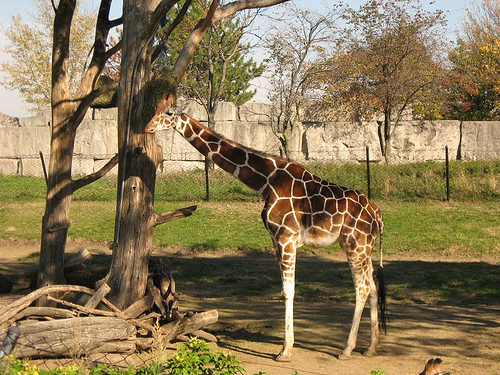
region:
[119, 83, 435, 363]
a giraffe by a tree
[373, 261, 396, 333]
long black hairs on tail of giraffe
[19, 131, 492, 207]
a fence with black posts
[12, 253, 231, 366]
a pile of logs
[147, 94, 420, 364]
white giraffe with brown patches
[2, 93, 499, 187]
a concrete wall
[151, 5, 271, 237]
a tree with no leaves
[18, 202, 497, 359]
shadow of tree on ground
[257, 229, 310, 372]
long front legs of giraffe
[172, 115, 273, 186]
long neck of giraffe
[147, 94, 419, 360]
giraffe standing in the forest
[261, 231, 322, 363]
leg of the giraffe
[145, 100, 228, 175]
leg of the giraffe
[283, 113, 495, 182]
compound of the zoo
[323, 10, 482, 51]
sky with clouds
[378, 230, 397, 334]
tail with fringes of the giraffe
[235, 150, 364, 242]
brown and cream color with polygons shape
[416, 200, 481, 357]
dirt with grass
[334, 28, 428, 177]
tree with branches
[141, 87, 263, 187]
head and neck of the giraffe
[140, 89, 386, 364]
Baby Giraffe Standing Up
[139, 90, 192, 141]
Giraffe laying it's head on the tree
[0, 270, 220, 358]
Pile of broken tree branches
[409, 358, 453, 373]
Top of another giraffes head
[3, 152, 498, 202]
Chain Link Fence Holding the giraffe in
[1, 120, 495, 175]
Stone Wall In The Background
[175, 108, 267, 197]
Giraffes long extended neck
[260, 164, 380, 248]
Giraffe's unique brown spots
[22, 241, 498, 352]
Shadow casted by the trees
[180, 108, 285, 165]
Thin Hairline on the giraffes neck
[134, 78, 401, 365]
a giraffe in a pen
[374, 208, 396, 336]
a long tail of giraffe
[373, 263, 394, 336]
turf of giraffe is black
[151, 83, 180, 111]
horns of giraffe are brown and black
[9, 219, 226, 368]
logs around the trunk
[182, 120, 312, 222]
spots of giraffe are large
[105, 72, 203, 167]
head of giraffe next a trunk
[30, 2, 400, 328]
giraffe near two trunks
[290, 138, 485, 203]
a wired fence of a pen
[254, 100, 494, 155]
rocks behind a fence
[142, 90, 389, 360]
Giraffe standing next to some trees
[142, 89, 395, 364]
Giraffe fenced in a zoo enclosure.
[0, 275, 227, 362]
Pile of wooden logs in a giraffe sanctuary.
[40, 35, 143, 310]
Trees with shadows on their trunks.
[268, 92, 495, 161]
Wall made of concrete slabs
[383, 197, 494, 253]
Grassy knoll in a giraffe sanctuary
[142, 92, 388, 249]
Spotted torso and neck of a giraffe.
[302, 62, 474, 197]
Tree with lightly colored foilage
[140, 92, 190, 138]
Giraffe's head facing the right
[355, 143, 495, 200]
Chain-link fence around a giraffe sanctuary.